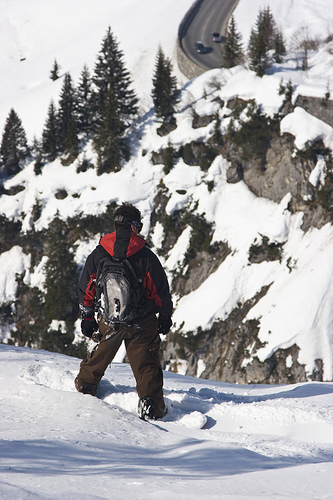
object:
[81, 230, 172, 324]
jacket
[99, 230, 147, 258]
hood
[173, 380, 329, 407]
shadow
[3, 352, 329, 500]
snow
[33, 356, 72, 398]
tracks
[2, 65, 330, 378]
mountain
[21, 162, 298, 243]
snow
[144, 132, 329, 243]
rock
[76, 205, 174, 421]
person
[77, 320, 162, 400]
pants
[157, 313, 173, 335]
glove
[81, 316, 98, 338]
glove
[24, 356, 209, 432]
snowboard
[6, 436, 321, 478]
shadows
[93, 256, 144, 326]
backpack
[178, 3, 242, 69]
road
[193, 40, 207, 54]
cars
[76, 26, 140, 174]
trees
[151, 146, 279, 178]
edges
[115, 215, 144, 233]
goggles